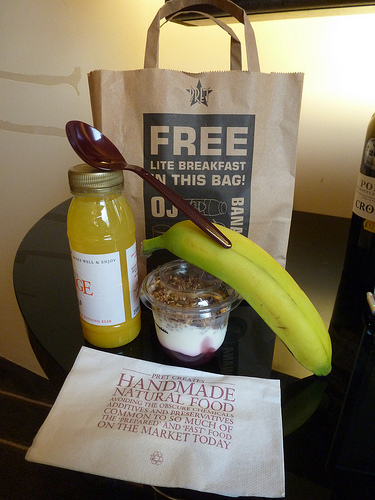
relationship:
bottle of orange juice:
[67, 164, 142, 347] [67, 198, 141, 350]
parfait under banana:
[138, 259, 245, 361] [141, 218, 332, 377]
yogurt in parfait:
[154, 316, 226, 355] [138, 259, 245, 361]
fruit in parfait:
[164, 346, 219, 363] [138, 259, 245, 361]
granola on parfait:
[151, 272, 228, 325] [138, 259, 245, 361]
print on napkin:
[95, 367, 236, 452] [25, 346, 286, 499]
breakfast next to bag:
[68, 166, 332, 376] [88, 1, 304, 287]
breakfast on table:
[68, 166, 332, 376] [13, 190, 352, 404]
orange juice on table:
[67, 198, 141, 350] [13, 190, 352, 404]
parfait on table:
[138, 259, 245, 361] [13, 190, 352, 404]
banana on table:
[141, 218, 332, 377] [13, 190, 352, 404]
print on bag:
[142, 113, 251, 238] [88, 1, 304, 287]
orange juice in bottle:
[67, 198, 141, 350] [67, 164, 142, 347]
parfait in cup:
[138, 259, 245, 361] [138, 257, 246, 365]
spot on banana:
[276, 327, 286, 333] [141, 218, 332, 377]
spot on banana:
[275, 315, 280, 320] [141, 218, 332, 377]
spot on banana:
[259, 303, 264, 308] [141, 218, 332, 377]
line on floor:
[2, 390, 51, 413] [1, 381, 154, 499]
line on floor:
[1, 437, 28, 450] [1, 381, 154, 499]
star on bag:
[185, 79, 213, 106] [88, 1, 304, 287]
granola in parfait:
[151, 272, 228, 325] [138, 259, 245, 361]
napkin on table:
[25, 346, 286, 499] [13, 190, 352, 404]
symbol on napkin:
[148, 451, 164, 466] [25, 346, 286, 499]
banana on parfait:
[141, 218, 332, 377] [138, 259, 245, 361]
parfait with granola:
[138, 259, 245, 361] [151, 272, 228, 325]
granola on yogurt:
[151, 272, 228, 325] [154, 316, 226, 355]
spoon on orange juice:
[67, 121, 233, 248] [67, 198, 141, 350]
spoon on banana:
[67, 121, 233, 248] [141, 218, 332, 377]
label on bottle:
[69, 243, 146, 328] [67, 164, 142, 347]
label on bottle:
[352, 172, 374, 233] [343, 114, 374, 257]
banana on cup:
[141, 218, 332, 377] [138, 257, 246, 365]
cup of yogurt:
[138, 257, 246, 365] [154, 316, 226, 355]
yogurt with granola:
[154, 316, 226, 355] [151, 272, 228, 325]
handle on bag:
[145, 2, 258, 73] [88, 1, 304, 287]